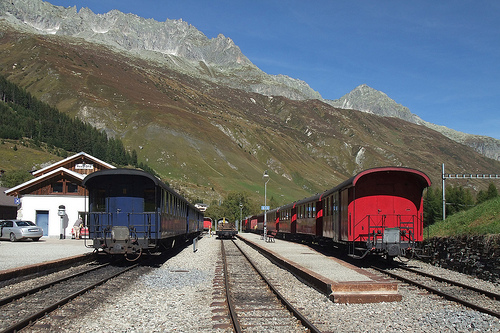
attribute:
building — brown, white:
[3, 165, 93, 244]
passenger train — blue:
[75, 165, 202, 267]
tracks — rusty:
[210, 232, 322, 331]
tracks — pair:
[378, 255, 498, 326]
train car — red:
[252, 203, 279, 237]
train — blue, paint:
[70, 150, 227, 259]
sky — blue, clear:
[47, 2, 498, 143]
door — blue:
[30, 205, 50, 235]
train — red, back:
[246, 166, 425, 263]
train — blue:
[84, 169, 203, 259]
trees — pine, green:
[1, 74, 156, 176]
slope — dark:
[4, 27, 497, 230]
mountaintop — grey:
[326, 80, 416, 115]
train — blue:
[74, 164, 207, 266]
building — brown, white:
[8, 149, 121, 241]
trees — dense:
[0, 74, 173, 187]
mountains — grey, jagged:
[0, 1, 499, 152]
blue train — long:
[78, 165, 208, 265]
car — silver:
[0, 213, 42, 244]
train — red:
[190, 164, 468, 281]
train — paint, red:
[251, 144, 455, 266]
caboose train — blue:
[85, 170, 167, 239]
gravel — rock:
[151, 252, 211, 331]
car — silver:
[0, 218, 44, 244]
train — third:
[212, 215, 241, 247]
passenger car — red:
[237, 205, 268, 241]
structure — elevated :
[435, 160, 497, 214]